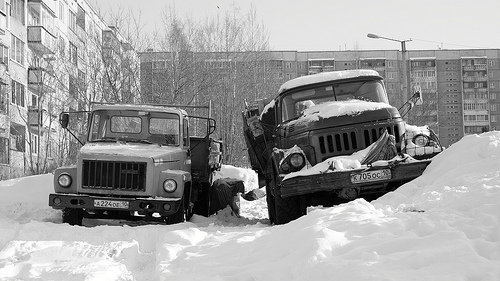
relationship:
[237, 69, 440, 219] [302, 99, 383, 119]
old vehicle with snow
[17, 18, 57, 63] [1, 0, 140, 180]
balcony on side of apartment building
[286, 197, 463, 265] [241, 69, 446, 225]
snow on old vehicle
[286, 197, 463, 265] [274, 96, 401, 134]
snow on hood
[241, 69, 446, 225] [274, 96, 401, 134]
old vehicle has hood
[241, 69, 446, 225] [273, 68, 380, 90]
old vehicle has roof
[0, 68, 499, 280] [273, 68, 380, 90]
snow on roof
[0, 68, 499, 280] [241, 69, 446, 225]
snow on old vehicle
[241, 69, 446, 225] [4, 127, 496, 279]
old vehicle parked on snow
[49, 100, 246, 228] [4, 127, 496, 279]
truck parked on snow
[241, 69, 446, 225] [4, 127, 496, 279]
old vehicle parked in snow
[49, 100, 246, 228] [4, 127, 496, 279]
truck parked in snow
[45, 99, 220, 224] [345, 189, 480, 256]
truck parked on snow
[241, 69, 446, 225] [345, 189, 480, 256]
old vehicle parked on snow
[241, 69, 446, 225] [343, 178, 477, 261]
old vehicle on snow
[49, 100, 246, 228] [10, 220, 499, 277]
truck on snow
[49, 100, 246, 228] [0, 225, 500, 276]
truck in snow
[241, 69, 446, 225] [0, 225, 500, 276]
old vehicle in snow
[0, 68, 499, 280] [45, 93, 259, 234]
snow on truck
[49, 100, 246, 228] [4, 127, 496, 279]
truck in snow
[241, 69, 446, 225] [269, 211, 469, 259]
old vehicle in snow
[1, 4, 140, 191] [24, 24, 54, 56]
apartment building with balcony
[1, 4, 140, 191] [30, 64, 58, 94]
apartment building with balcony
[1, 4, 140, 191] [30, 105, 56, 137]
apartment building with balcony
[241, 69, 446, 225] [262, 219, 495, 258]
old vehicle on snow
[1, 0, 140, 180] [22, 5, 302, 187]
apartment building with balconies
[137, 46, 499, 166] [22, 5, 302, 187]
building with balconies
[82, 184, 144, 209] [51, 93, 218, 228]
plate on truck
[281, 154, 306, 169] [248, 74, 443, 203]
light on truck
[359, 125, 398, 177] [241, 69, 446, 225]
trash on old vehicle